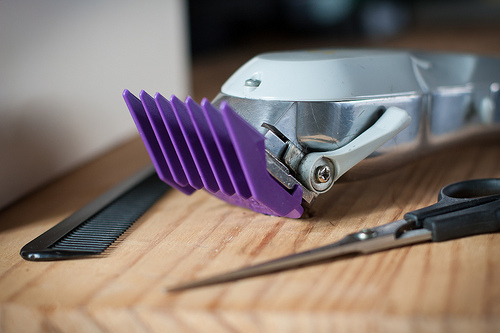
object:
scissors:
[164, 178, 499, 294]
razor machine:
[122, 48, 499, 220]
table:
[2, 29, 497, 333]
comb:
[19, 167, 170, 262]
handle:
[404, 178, 497, 242]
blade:
[122, 88, 304, 219]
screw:
[356, 232, 370, 240]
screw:
[316, 166, 331, 183]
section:
[210, 50, 499, 204]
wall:
[1, 0, 191, 212]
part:
[122, 86, 213, 197]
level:
[298, 106, 413, 194]